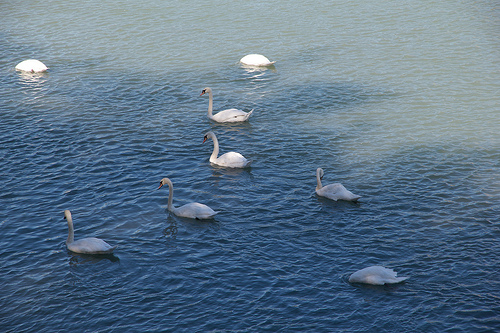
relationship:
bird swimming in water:
[348, 260, 413, 285] [1, 6, 496, 330]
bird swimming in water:
[315, 165, 364, 204] [1, 6, 496, 330]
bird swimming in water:
[155, 175, 218, 221] [1, 6, 496, 330]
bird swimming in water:
[58, 206, 116, 258] [1, 6, 496, 330]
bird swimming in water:
[311, 166, 362, 205] [1, 6, 496, 330]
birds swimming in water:
[187, 74, 267, 134] [1, 6, 496, 330]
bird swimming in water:
[13, 57, 49, 77] [1, 6, 496, 330]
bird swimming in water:
[196, 128, 258, 170] [1, 6, 496, 330]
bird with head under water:
[348, 264, 411, 290] [347, 72, 452, 164]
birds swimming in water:
[188, 82, 262, 126] [1, 6, 496, 330]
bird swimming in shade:
[58, 206, 116, 258] [3, 38, 498, 330]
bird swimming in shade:
[152, 175, 220, 222] [3, 38, 498, 330]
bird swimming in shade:
[311, 166, 362, 205] [3, 38, 498, 330]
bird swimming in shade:
[196, 128, 258, 171] [3, 38, 498, 330]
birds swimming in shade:
[188, 82, 262, 126] [3, 38, 498, 330]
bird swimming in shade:
[311, 166, 362, 205] [3, 65, 494, 331]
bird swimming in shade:
[348, 264, 411, 290] [3, 65, 494, 331]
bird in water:
[58, 206, 116, 258] [1, 6, 496, 330]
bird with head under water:
[196, 128, 258, 171] [1, 6, 496, 330]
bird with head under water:
[237, 52, 278, 67] [1, 6, 496, 330]